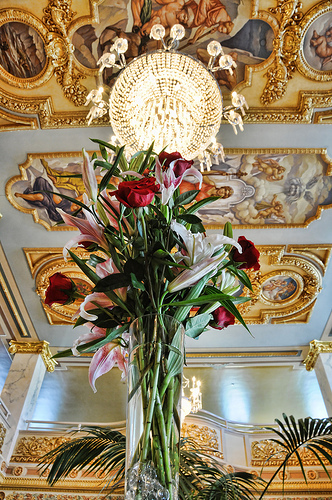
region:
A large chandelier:
[88, 28, 255, 155]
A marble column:
[3, 350, 39, 459]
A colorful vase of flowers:
[37, 156, 252, 495]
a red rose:
[43, 270, 81, 306]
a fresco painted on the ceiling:
[189, 141, 322, 227]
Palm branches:
[188, 421, 328, 492]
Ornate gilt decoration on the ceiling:
[254, 6, 316, 112]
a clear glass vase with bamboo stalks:
[122, 331, 186, 493]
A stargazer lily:
[66, 323, 125, 392]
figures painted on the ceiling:
[120, 5, 239, 36]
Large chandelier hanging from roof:
[83, 22, 247, 181]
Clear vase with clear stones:
[116, 316, 190, 495]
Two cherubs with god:
[249, 147, 321, 232]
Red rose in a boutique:
[114, 170, 156, 225]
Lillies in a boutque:
[50, 188, 115, 271]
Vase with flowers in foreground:
[62, 128, 247, 495]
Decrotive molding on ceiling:
[18, 236, 328, 333]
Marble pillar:
[4, 346, 48, 463]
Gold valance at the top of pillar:
[8, 335, 63, 372]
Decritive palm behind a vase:
[46, 418, 296, 499]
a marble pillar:
[0, 344, 49, 475]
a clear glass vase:
[116, 310, 187, 495]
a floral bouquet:
[29, 135, 271, 494]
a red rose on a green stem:
[39, 269, 119, 328]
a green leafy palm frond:
[249, 407, 329, 494]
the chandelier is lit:
[83, 17, 250, 171]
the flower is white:
[166, 218, 245, 263]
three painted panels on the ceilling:
[0, 0, 329, 335]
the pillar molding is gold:
[4, 334, 57, 373]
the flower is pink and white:
[55, 195, 111, 259]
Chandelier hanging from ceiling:
[79, 22, 249, 171]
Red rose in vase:
[115, 175, 165, 324]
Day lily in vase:
[152, 147, 200, 232]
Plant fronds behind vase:
[35, 403, 328, 496]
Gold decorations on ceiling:
[235, 243, 328, 321]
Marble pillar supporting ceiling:
[1, 339, 56, 463]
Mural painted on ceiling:
[172, 146, 326, 229]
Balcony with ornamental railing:
[0, 405, 326, 488]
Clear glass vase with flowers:
[121, 312, 181, 496]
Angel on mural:
[242, 153, 288, 187]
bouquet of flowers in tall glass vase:
[28, 140, 262, 481]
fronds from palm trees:
[190, 406, 320, 492]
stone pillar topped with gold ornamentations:
[4, 335, 50, 451]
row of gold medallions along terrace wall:
[199, 452, 324, 490]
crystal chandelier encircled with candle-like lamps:
[67, 10, 250, 178]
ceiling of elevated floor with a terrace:
[216, 372, 315, 407]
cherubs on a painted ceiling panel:
[244, 139, 288, 232]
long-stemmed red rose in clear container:
[106, 166, 169, 415]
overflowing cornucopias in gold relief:
[34, 0, 91, 103]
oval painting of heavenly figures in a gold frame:
[253, 265, 312, 310]